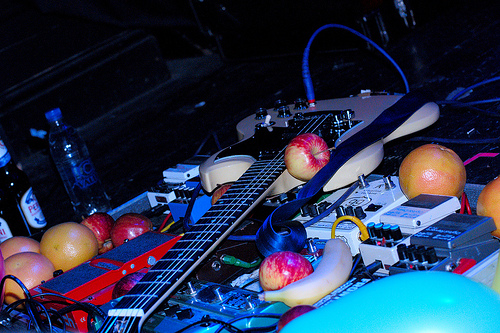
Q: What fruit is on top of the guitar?
A: Apple.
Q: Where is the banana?
A: On top of sound equipment.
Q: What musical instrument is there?
A: Guitar.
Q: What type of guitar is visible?
A: Electrical guitar.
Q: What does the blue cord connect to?
A: Guitar.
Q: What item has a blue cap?
A: Bottle of water.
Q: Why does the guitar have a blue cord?
A: Because it's electric.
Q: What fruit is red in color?
A: Apple.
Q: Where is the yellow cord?
A: Above banana.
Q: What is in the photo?
A: Water bottle.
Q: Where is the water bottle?
A: In the photo.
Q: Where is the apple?
A: Next to the banana.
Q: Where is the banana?
A: Next to the apple.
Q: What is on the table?
A: A guitar.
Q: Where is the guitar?
A: On the table.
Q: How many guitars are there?
A: One.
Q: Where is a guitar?
A: On the table.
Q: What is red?
A: Apples.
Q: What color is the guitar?
A: White.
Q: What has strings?
A: Guitar.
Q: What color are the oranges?
A: Orange.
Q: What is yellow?
A: Banana.